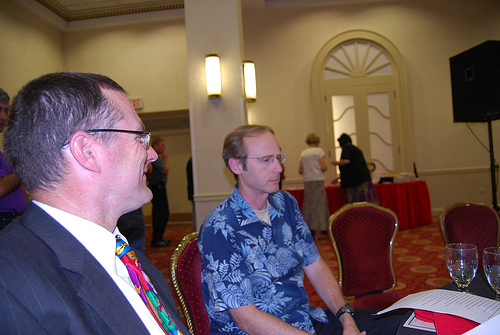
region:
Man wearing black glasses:
[21, 51, 190, 192]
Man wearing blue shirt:
[202, 186, 319, 324]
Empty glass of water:
[425, 222, 493, 309]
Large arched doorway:
[300, 10, 463, 210]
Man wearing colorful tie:
[102, 232, 195, 332]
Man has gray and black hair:
[13, 45, 133, 213]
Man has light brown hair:
[211, 114, 273, 174]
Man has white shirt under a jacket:
[36, 202, 164, 329]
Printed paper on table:
[383, 280, 450, 332]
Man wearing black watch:
[319, 288, 364, 327]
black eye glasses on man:
[77, 114, 174, 150]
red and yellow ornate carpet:
[320, 201, 465, 293]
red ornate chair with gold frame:
[327, 189, 401, 294]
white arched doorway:
[326, 12, 413, 154]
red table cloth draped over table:
[277, 173, 437, 242]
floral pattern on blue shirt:
[216, 183, 309, 296]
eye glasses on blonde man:
[234, 143, 299, 183]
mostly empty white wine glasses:
[438, 235, 491, 288]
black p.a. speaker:
[444, 38, 499, 160]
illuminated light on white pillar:
[198, 44, 278, 104]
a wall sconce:
[204, 52, 225, 103]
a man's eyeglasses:
[46, 127, 151, 151]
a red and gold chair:
[324, 199, 406, 311]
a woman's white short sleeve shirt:
[295, 147, 327, 184]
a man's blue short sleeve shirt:
[196, 185, 321, 330]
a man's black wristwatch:
[330, 301, 355, 317]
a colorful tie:
[115, 233, 184, 333]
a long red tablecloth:
[290, 177, 432, 229]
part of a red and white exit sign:
[127, 92, 146, 109]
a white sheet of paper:
[370, 276, 497, 326]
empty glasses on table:
[435, 236, 497, 298]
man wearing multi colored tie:
[102, 231, 188, 327]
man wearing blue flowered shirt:
[207, 187, 346, 326]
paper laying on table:
[385, 265, 497, 317]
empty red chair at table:
[331, 197, 411, 308]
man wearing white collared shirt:
[60, 205, 175, 320]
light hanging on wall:
[200, 47, 230, 107]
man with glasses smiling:
[99, 107, 174, 217]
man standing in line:
[152, 134, 186, 244]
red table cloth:
[394, 187, 441, 229]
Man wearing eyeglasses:
[132, 129, 154, 146]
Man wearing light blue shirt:
[214, 224, 292, 285]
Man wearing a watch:
[337, 301, 357, 318]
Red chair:
[338, 213, 391, 282]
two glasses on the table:
[446, 241, 498, 283]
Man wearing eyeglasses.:
[246, 149, 288, 171]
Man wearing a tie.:
[122, 242, 146, 288]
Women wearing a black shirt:
[343, 142, 366, 179]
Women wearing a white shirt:
[302, 145, 325, 182]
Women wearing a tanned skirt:
[303, 178, 331, 209]